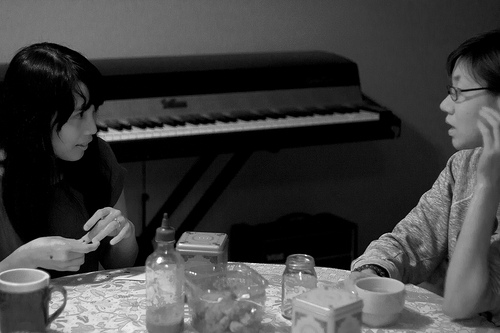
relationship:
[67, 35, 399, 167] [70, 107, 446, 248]
piano on table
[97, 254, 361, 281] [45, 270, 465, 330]
edge of a table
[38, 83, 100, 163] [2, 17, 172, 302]
face of a girl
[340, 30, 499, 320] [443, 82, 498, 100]
lady wearing glasses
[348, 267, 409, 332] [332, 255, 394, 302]
cup in a hand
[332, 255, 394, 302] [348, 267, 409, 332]
hand holding cup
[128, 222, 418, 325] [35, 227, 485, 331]
cups on top of table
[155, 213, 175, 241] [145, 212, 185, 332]
teat pipette on jar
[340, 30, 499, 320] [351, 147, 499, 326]
lady wearing sweater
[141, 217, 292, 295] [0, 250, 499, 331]
boxes on top of table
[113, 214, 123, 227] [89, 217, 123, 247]
ring on finger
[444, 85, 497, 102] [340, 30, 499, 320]
glasses on lady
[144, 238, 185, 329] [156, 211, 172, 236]
bottle has teat pipette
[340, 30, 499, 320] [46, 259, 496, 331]
lady across table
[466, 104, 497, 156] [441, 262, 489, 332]
hand on elbow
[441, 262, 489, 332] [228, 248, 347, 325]
elbow on table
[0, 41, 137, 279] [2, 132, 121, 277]
girl wearing dark outfit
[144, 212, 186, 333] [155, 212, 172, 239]
bottle has cap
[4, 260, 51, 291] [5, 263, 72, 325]
border around mug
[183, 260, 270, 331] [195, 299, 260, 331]
bag containing fruit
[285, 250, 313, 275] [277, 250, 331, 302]
lid on canister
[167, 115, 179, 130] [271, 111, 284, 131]
key above key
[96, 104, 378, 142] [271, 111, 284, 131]
key above key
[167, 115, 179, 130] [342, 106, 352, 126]
key above key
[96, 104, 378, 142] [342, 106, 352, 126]
key above key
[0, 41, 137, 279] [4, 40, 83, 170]
girl has hair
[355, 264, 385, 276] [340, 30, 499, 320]
beads on wrist of lady